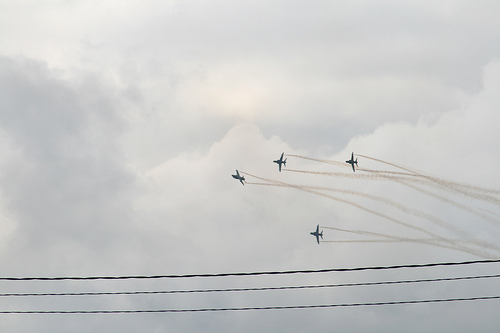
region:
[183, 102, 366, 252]
fighter jets in the sky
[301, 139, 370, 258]
fighter jets in the sky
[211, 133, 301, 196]
fighter jets in the sky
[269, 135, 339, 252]
fighter jets in the sky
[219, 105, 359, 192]
fighter jets in the sky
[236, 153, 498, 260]
Smoke trailing behind the jets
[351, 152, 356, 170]
The wing of the jet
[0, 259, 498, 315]
Electrical wires beneath the jets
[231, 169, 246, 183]
A jet flying in the air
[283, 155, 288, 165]
The tail of the airplane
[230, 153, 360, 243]
Jets flying in the sky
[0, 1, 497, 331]
The sky above the airplanes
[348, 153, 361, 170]
The jet is trailing smoke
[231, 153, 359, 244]
The jets are flying as a group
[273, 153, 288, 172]
The jet is flying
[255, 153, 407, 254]
airplanes in the sky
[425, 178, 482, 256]
exhaust from the planes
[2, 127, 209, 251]
clouds in the sky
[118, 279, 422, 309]
the powerlines are hanging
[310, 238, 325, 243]
wing of the plane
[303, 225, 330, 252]
silhouette of the plane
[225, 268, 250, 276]
the powerline is black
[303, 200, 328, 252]
this is a plane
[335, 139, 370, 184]
this is a plane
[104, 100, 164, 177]
this is a cloud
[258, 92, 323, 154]
this is a cloud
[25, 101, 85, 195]
this is a cloud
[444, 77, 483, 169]
this is a cloud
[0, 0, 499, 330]
sky is white and cloudy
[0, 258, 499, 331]
black electrical wires together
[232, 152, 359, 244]
planes are flying together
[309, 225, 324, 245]
plane flying on the bottom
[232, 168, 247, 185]
plane flying in the front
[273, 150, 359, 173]
planes flying on top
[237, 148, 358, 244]
planes are doing tricks in the air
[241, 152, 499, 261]
streaks of smoke in the air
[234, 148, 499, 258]
planes leaving behind smoke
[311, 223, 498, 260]
bottom plane is leave a trail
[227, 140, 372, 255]
four planes flying together